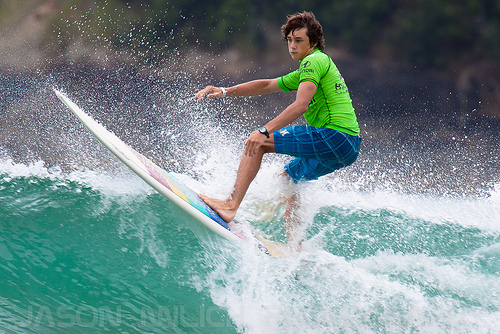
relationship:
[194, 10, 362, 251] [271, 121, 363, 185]
male wearing shorts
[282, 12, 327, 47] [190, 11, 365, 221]
hair on head of male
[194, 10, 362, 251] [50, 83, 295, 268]
male riding on a board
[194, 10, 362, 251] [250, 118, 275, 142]
male wearing a watch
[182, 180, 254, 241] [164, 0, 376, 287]
foot on leg of man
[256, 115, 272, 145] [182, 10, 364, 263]
watch on wrist of person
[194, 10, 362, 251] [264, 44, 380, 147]
male wearing a shirt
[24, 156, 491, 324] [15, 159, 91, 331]
wave in ocean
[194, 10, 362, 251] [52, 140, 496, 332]
male riding wave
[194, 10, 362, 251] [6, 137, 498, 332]
male overcoming wave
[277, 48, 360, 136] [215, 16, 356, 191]
green shirt on surfer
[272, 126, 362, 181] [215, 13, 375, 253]
shorts on surfer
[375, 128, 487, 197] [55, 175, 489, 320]
spray off wave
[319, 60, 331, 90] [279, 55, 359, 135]
stitching on green shirt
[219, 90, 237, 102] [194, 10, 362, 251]
wrist on male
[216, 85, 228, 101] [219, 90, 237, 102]
band on wrist